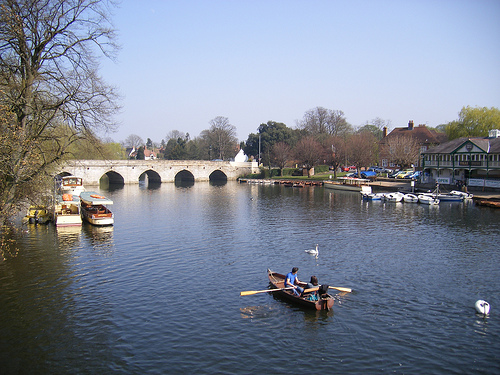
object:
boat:
[267, 268, 335, 311]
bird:
[304, 243, 319, 255]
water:
[0, 181, 499, 374]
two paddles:
[240, 286, 352, 296]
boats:
[417, 195, 441, 205]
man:
[283, 266, 305, 296]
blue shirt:
[284, 272, 297, 286]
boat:
[22, 202, 49, 226]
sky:
[0, 0, 500, 145]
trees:
[262, 140, 299, 176]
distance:
[0, 132, 194, 161]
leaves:
[48, 148, 57, 153]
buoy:
[90, 194, 105, 199]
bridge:
[49, 159, 261, 187]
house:
[376, 120, 440, 171]